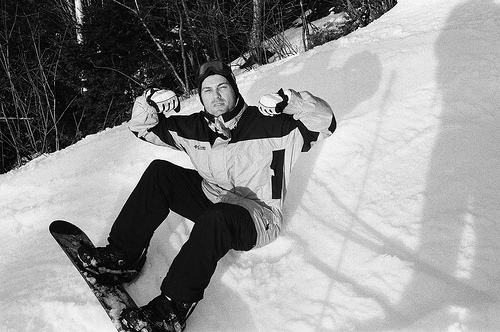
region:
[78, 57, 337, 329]
A man making muscles in the snow.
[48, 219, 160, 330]
A black snowboard in the snow.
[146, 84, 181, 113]
A black and white right hand glove.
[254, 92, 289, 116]
A black and white left hand glove.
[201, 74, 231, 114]
The squinty eyed face of a man in the snow.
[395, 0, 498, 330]
Shadow of a person standing.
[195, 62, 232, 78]
Black goggles on the head of a man in the snow.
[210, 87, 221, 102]
Nose on the face of a man in the snow.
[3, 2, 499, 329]
A white snow slope.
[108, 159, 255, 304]
Black pants on a man in the snow.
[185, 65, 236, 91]
man has dark hat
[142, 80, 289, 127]
man has white gloves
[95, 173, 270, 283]
man has black pants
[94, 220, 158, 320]
man has black shoes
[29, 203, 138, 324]
man has black snowboard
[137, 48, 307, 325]
man sitting in snow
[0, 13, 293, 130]
bare trees behind man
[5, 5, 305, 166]
bare branches over dark area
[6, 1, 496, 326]
man seated on slope of snow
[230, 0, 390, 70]
trees and plantings in snow behind slope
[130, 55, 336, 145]
man with bent elbows and curled hands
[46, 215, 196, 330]
feet on dark snow-covered snowboard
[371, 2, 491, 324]
shadow of standing figure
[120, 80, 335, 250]
blocks of contrasting color on jacket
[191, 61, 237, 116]
face of curved eyebrows, eyes and mustache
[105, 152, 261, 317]
bent knees in dark pants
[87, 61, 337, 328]
snowboarder in white snow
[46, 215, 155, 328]
black snowboard in white snow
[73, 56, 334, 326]
man wearing black and whtie jacket and black pants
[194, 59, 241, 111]
black balaclaa on man's head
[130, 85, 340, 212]
big warmy jacket of man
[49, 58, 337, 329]
Male snowboarder sitting in snow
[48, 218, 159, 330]
Snowboard attached to person's feet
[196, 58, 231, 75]
Snow goggles on man's head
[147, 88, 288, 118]
Pair of gloves worn on man's hands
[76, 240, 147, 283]
Heavy snowboarder's boot attached to snowboard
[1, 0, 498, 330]
Steep slope covered in snow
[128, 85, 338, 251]
Light colored coat with dark trim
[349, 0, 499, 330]
Shadow on snow of an unseen person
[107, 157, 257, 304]
Heavy dark pants worn by snowboarder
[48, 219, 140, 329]
dark snowboard on top of snow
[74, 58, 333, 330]
man is wearing black pants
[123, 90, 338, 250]
man wearing a ski jacket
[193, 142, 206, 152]
logo embroidered on jacket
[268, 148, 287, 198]
dark stripe sewn onto jacket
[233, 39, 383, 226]
shadow behind man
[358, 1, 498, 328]
shadow to the right of man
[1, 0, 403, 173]
trees behind man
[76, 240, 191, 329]
boots touching snowboard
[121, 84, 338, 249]
black and white jacket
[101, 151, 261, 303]
pair of black pants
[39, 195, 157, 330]
large black snow board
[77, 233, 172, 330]
a pair of black shoes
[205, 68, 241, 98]
a black ski hat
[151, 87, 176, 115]
a white and grey glove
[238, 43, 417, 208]
shadow on the snow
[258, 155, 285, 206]
pocket on a coat